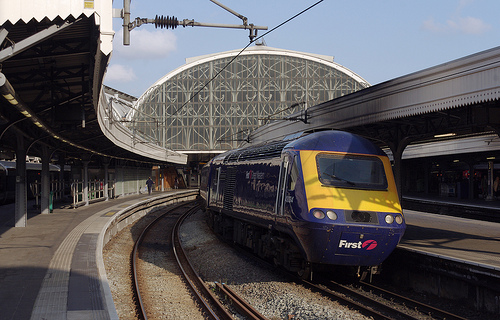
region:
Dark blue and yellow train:
[192, 128, 407, 285]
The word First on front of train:
[277, 128, 410, 280]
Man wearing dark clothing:
[137, 169, 162, 199]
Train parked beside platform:
[186, 125, 497, 315]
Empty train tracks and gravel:
[128, 199, 236, 319]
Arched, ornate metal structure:
[128, 58, 375, 146]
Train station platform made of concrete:
[9, 179, 195, 318]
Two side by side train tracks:
[127, 185, 465, 317]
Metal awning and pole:
[6, 63, 192, 171]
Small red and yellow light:
[460, 163, 473, 182]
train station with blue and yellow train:
[4, 19, 498, 319]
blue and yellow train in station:
[198, 128, 408, 278]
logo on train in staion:
[336, 238, 378, 250]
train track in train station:
[138, 191, 425, 318]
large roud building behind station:
[122, 42, 373, 151]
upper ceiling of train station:
[0, 0, 189, 175]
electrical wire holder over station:
[118, 0, 268, 45]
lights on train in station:
[308, 208, 407, 225]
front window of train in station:
[313, 151, 391, 192]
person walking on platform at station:
[144, 177, 153, 193]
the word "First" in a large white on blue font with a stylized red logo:
[338, 237, 376, 251]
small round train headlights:
[309, 207, 406, 228]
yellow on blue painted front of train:
[286, 127, 406, 232]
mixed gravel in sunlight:
[254, 285, 353, 318]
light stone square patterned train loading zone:
[36, 222, 103, 319]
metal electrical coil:
[153, 12, 180, 32]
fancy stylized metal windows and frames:
[214, 66, 299, 114]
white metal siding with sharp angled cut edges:
[0, 1, 111, 53]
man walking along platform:
[143, 175, 155, 197]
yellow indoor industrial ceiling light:
[433, 132, 458, 140]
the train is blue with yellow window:
[141, 103, 418, 272]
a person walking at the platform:
[139, 167, 159, 207]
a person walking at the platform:
[121, 154, 203, 224]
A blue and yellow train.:
[191, 134, 416, 274]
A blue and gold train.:
[192, 126, 406, 284]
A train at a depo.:
[16, 38, 431, 309]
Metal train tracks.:
[127, 177, 205, 313]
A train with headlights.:
[290, 123, 414, 287]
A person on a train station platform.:
[133, 158, 167, 218]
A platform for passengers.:
[28, 8, 155, 313]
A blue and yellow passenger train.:
[174, 92, 454, 298]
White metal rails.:
[25, 170, 113, 215]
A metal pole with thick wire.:
[137, 12, 269, 149]